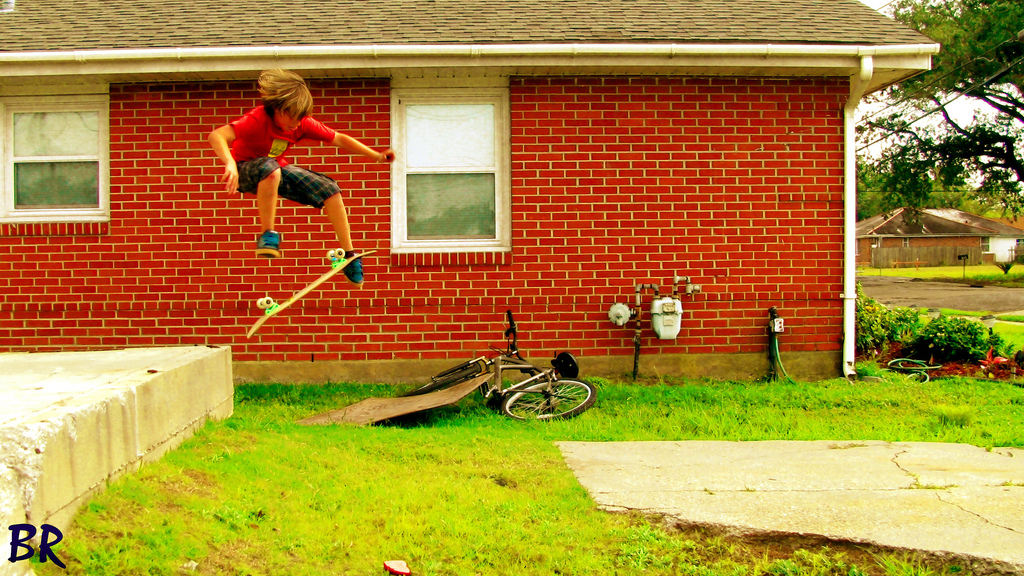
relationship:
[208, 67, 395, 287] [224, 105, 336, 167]
boy wearing shirt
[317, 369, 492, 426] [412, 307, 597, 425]
wood piece on top of bike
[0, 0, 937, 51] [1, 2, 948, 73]
roof are on roof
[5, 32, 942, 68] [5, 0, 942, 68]
drain pipe along roof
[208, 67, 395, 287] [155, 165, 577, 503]
boy jumping in air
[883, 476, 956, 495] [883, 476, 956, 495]
grass growing in a crack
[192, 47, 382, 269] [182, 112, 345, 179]
boy wearing shirt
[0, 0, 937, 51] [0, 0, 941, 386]
roof on building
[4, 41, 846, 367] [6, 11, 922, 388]
wal on building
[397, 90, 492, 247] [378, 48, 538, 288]
window has frame